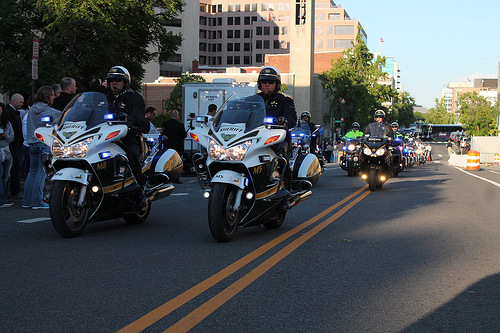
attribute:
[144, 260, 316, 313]
lines — yellow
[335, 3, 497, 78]
sky — clear, blue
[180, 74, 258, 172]
ambulance — white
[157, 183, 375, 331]
line — yellow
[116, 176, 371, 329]
line — yellow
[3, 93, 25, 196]
person — spectating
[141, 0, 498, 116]
buildings — tall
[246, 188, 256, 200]
light — on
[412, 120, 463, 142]
bus — large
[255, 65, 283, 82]
helmet — white, blue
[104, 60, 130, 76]
helmet — white, blue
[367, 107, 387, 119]
helmet — white, blue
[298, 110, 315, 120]
helmet — white, blue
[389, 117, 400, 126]
helmet — white, blue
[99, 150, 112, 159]
light — blue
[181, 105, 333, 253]
bike — white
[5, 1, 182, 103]
tree — green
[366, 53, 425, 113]
building — tall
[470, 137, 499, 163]
wall — tall, white, retaining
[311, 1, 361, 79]
wall — retaining, tall, white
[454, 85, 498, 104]
wall — retaining, tall, white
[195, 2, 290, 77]
wall — retaining, tall, white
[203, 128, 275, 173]
lights — on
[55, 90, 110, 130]
windshield — glassy